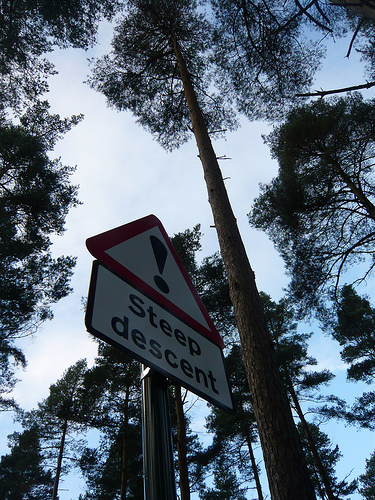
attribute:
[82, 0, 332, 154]
tree — large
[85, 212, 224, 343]
sign — red and white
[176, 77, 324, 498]
trunk — tall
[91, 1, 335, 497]
trees — tall pine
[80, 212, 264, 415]
sign — black and white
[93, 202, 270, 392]
sign —  red, black and white 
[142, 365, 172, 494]
post — metal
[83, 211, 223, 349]
triangle — black, white, red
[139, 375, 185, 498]
pole — metal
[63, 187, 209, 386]
sign — black, white, rectangular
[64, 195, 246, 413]
sign — black, white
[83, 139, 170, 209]
sky — clear, blue